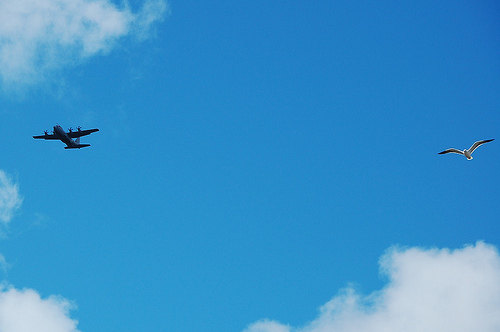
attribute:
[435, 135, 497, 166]
seagull — in flight, flying, bird, feathered, white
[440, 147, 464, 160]
wing — gliding, white, black topped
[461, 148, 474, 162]
body — white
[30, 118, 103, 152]
airplane — in flight, prop plane, grey, flying, white, in air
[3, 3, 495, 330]
sky — blue, partially cloudless, partially clear, partially cloudy, clear, faded cloudy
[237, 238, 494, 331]
cloud — gray, white, fluffy, big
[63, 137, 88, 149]
tail — grey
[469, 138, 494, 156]
wing — black topped